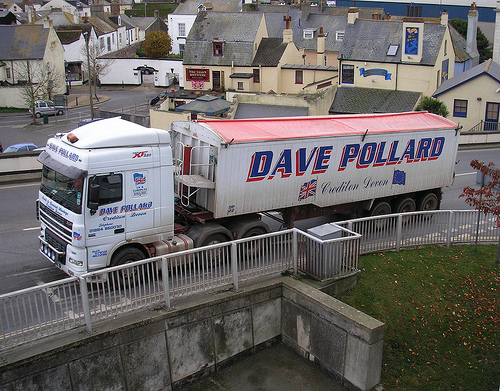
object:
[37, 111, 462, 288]
truck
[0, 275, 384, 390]
wall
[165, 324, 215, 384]
cement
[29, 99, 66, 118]
vehicle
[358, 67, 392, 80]
signs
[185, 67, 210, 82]
sign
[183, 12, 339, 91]
building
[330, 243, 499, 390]
grass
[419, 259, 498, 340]
leaves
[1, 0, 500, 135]
group of buildings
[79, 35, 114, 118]
tree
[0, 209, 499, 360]
fence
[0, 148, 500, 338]
road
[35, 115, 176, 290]
cab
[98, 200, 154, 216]
lettering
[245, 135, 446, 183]
lettering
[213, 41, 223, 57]
window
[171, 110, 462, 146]
roof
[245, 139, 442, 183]
red trim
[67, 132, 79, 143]
light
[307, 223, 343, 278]
box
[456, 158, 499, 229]
leaves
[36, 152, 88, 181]
visor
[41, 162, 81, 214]
window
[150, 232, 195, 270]
tank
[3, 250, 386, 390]
bridge